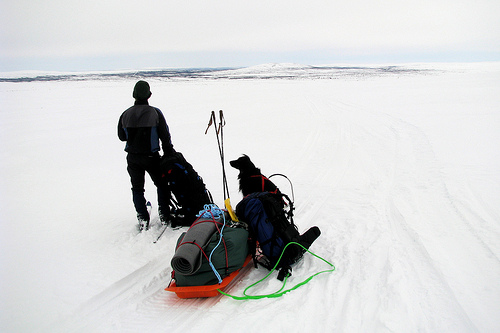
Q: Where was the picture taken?
A: It was taken at the field.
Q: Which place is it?
A: It is a field.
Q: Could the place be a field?
A: Yes, it is a field.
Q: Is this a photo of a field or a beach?
A: It is showing a field.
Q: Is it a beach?
A: No, it is a field.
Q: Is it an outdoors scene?
A: Yes, it is outdoors.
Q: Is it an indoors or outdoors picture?
A: It is outdoors.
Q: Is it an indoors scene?
A: No, it is outdoors.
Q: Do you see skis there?
A: Yes, there are skis.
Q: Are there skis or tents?
A: Yes, there are skis.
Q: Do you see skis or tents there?
A: Yes, there are skis.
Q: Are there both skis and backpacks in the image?
A: Yes, there are both skis and a backpack.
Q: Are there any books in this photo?
A: No, there are no books.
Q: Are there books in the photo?
A: No, there are no books.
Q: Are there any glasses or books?
A: No, there are no books or glasses.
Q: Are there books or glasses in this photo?
A: No, there are no books or glasses.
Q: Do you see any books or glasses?
A: No, there are no books or glasses.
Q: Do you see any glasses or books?
A: No, there are no books or glasses.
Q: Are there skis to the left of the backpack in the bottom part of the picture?
A: Yes, there are skis to the left of the backpack.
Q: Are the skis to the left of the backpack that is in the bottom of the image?
A: Yes, the skis are to the left of the backpack.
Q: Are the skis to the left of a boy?
A: No, the skis are to the left of the backpack.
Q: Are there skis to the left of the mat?
A: Yes, there are skis to the left of the mat.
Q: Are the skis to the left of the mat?
A: Yes, the skis are to the left of the mat.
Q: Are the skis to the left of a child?
A: No, the skis are to the left of the mat.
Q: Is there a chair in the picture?
A: Yes, there is a chair.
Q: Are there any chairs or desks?
A: Yes, there is a chair.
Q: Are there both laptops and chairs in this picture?
A: No, there is a chair but no laptops.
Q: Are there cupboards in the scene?
A: No, there are no cupboards.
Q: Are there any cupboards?
A: No, there are no cupboards.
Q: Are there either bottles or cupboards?
A: No, there are no cupboards or bottles.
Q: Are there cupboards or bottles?
A: No, there are no cupboards or bottles.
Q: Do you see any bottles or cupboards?
A: No, there are no cupboards or bottles.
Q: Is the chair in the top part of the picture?
A: No, the chair is in the bottom of the image.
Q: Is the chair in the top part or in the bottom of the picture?
A: The chair is in the bottom of the image.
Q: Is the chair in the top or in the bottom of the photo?
A: The chair is in the bottom of the image.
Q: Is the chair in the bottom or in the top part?
A: The chair is in the bottom of the image.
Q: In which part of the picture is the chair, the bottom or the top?
A: The chair is in the bottom of the image.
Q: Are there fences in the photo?
A: No, there are no fences.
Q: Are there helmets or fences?
A: No, there are no fences or helmets.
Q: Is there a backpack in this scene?
A: Yes, there is a backpack.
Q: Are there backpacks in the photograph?
A: Yes, there is a backpack.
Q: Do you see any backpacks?
A: Yes, there is a backpack.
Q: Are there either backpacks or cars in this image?
A: Yes, there is a backpack.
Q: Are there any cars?
A: No, there are no cars.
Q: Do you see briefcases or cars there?
A: No, there are no cars or briefcases.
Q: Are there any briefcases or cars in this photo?
A: No, there are no cars or briefcases.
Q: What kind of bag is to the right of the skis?
A: The bag is a backpack.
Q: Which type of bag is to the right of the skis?
A: The bag is a backpack.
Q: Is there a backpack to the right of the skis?
A: Yes, there is a backpack to the right of the skis.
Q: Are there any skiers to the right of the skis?
A: No, there is a backpack to the right of the skis.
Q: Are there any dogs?
A: Yes, there is a dog.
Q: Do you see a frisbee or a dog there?
A: Yes, there is a dog.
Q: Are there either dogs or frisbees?
A: Yes, there is a dog.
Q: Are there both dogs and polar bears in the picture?
A: No, there is a dog but no polar bears.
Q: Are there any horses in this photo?
A: No, there are no horses.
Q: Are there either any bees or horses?
A: No, there are no horses or bees.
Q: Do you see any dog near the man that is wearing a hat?
A: Yes, there is a dog near the man.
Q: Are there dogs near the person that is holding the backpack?
A: Yes, there is a dog near the man.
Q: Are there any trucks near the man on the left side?
A: No, there is a dog near the man.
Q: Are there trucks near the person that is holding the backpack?
A: No, there is a dog near the man.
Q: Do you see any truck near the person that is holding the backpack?
A: No, there is a dog near the man.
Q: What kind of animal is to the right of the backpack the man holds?
A: The animal is a dog.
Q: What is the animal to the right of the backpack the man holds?
A: The animal is a dog.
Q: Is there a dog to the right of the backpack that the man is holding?
A: Yes, there is a dog to the right of the backpack.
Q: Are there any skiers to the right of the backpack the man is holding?
A: No, there is a dog to the right of the backpack.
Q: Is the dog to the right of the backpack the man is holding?
A: Yes, the dog is to the right of the backpack.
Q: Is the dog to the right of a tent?
A: No, the dog is to the right of the backpack.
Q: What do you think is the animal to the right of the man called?
A: The animal is a dog.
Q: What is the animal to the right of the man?
A: The animal is a dog.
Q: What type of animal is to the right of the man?
A: The animal is a dog.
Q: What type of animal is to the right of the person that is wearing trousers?
A: The animal is a dog.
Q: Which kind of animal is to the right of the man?
A: The animal is a dog.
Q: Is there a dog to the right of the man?
A: Yes, there is a dog to the right of the man.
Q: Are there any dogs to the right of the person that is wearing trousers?
A: Yes, there is a dog to the right of the man.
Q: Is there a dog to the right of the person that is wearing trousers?
A: Yes, there is a dog to the right of the man.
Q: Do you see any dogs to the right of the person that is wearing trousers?
A: Yes, there is a dog to the right of the man.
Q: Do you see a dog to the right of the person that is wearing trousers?
A: Yes, there is a dog to the right of the man.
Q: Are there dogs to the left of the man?
A: No, the dog is to the right of the man.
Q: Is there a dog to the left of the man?
A: No, the dog is to the right of the man.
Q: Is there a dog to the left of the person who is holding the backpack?
A: No, the dog is to the right of the man.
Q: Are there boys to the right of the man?
A: No, there is a dog to the right of the man.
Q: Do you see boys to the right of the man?
A: No, there is a dog to the right of the man.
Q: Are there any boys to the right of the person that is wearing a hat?
A: No, there is a dog to the right of the man.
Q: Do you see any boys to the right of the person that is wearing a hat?
A: No, there is a dog to the right of the man.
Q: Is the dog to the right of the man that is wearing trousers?
A: Yes, the dog is to the right of the man.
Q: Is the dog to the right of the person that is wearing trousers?
A: Yes, the dog is to the right of the man.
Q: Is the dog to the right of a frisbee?
A: No, the dog is to the right of the man.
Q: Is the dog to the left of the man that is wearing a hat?
A: No, the dog is to the right of the man.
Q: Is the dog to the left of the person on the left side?
A: No, the dog is to the right of the man.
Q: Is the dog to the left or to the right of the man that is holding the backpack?
A: The dog is to the right of the man.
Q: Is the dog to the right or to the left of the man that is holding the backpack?
A: The dog is to the right of the man.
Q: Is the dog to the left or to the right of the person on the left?
A: The dog is to the right of the man.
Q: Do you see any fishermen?
A: No, there are no fishermen.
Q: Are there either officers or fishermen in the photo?
A: No, there are no fishermen or officers.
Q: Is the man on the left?
A: Yes, the man is on the left of the image.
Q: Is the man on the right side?
A: No, the man is on the left of the image.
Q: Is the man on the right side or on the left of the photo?
A: The man is on the left of the image.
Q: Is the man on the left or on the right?
A: The man is on the left of the image.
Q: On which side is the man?
A: The man is on the left of the image.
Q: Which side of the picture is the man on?
A: The man is on the left of the image.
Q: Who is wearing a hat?
A: The man is wearing a hat.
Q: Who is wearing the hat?
A: The man is wearing a hat.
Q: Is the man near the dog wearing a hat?
A: Yes, the man is wearing a hat.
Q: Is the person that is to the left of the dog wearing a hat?
A: Yes, the man is wearing a hat.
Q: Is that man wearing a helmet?
A: No, the man is wearing a hat.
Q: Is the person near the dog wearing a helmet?
A: No, the man is wearing a hat.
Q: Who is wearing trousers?
A: The man is wearing trousers.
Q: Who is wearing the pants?
A: The man is wearing trousers.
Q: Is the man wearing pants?
A: Yes, the man is wearing pants.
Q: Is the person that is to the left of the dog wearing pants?
A: Yes, the man is wearing pants.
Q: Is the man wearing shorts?
A: No, the man is wearing pants.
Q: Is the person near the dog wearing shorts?
A: No, the man is wearing pants.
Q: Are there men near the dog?
A: Yes, there is a man near the dog.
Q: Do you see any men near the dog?
A: Yes, there is a man near the dog.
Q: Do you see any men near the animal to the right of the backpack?
A: Yes, there is a man near the dog.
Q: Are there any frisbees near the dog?
A: No, there is a man near the dog.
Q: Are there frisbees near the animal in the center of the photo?
A: No, there is a man near the dog.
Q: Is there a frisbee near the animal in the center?
A: No, there is a man near the dog.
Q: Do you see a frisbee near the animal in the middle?
A: No, there is a man near the dog.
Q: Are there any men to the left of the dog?
A: Yes, there is a man to the left of the dog.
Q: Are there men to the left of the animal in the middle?
A: Yes, there is a man to the left of the dog.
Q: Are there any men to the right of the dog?
A: No, the man is to the left of the dog.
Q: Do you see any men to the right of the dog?
A: No, the man is to the left of the dog.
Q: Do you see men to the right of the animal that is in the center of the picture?
A: No, the man is to the left of the dog.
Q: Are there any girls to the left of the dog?
A: No, there is a man to the left of the dog.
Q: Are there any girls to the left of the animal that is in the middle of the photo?
A: No, there is a man to the left of the dog.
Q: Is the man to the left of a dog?
A: Yes, the man is to the left of a dog.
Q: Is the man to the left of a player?
A: No, the man is to the left of a dog.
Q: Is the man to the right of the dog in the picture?
A: No, the man is to the left of the dog.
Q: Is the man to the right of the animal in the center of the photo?
A: No, the man is to the left of the dog.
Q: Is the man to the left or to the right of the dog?
A: The man is to the left of the dog.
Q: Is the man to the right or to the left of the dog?
A: The man is to the left of the dog.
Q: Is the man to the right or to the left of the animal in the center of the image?
A: The man is to the left of the dog.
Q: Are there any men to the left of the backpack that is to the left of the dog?
A: Yes, there is a man to the left of the backpack.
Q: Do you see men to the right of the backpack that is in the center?
A: No, the man is to the left of the backpack.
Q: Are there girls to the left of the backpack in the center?
A: No, there is a man to the left of the backpack.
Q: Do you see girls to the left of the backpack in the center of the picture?
A: No, there is a man to the left of the backpack.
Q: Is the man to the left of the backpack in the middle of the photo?
A: Yes, the man is to the left of the backpack.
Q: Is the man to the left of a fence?
A: No, the man is to the left of the backpack.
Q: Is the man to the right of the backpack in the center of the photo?
A: No, the man is to the left of the backpack.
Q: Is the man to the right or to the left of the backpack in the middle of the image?
A: The man is to the left of the backpack.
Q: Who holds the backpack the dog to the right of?
A: The man holds the backpack.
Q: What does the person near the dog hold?
A: The man holds the backpack.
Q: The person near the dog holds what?
A: The man holds the backpack.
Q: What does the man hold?
A: The man holds the backpack.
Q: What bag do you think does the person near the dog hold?
A: The man holds the backpack.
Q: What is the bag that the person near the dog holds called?
A: The bag is a backpack.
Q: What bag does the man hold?
A: The man holds the backpack.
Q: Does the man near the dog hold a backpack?
A: Yes, the man holds a backpack.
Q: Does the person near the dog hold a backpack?
A: Yes, the man holds a backpack.